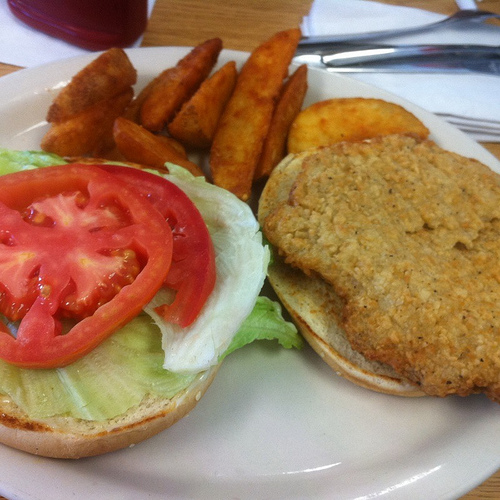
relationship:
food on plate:
[0, 28, 500, 460] [28, 318, 468, 497]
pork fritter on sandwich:
[260, 133, 497, 403] [0, 131, 499, 461]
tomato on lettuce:
[0, 163, 216, 370] [1, 147, 305, 421]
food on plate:
[0, 28, 500, 460] [0, 30, 488, 497]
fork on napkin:
[294, 8, 496, 55] [294, 0, 499, 144]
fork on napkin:
[294, 8, 500, 73] [294, 0, 499, 144]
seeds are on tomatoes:
[117, 247, 139, 276] [0, 158, 214, 355]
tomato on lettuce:
[1, 167, 205, 371] [1, 147, 305, 421]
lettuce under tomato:
[197, 183, 251, 284] [17, 167, 174, 311]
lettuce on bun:
[1, 147, 305, 421] [3, 372, 215, 464]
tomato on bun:
[1, 167, 205, 371] [3, 372, 215, 464]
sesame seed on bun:
[193, 390, 202, 402] [1, 155, 276, 460]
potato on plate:
[291, 97, 426, 144] [291, 52, 498, 175]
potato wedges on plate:
[45, 26, 430, 196] [0, 30, 488, 497]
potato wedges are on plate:
[45, 26, 430, 196] [0, 30, 488, 497]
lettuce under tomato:
[1, 147, 305, 421] [1, 167, 205, 371]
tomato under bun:
[1, 167, 205, 371] [12, 142, 235, 471]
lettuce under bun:
[1, 147, 305, 421] [12, 142, 235, 471]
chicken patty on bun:
[276, 132, 498, 394] [254, 136, 498, 403]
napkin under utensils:
[294, 0, 499, 144] [299, 32, 497, 73]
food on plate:
[0, 28, 500, 460] [0, 334, 497, 499]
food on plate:
[204, 21, 308, 186] [0, 30, 488, 497]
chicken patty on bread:
[261, 132, 500, 402] [256, 137, 449, 399]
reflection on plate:
[272, 459, 345, 480] [0, 30, 488, 497]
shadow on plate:
[450, 399, 490, 412] [13, 395, 490, 499]